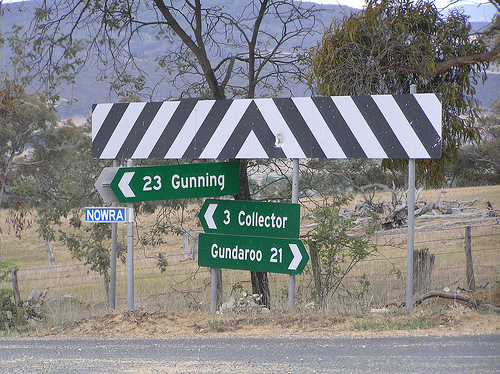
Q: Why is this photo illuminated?
A: Sunlight.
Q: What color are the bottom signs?
A: Green.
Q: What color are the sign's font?
A: White.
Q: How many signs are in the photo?
A: 4.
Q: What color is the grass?
A: Brown.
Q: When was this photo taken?
A: During the day.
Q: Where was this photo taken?
A: On the street.